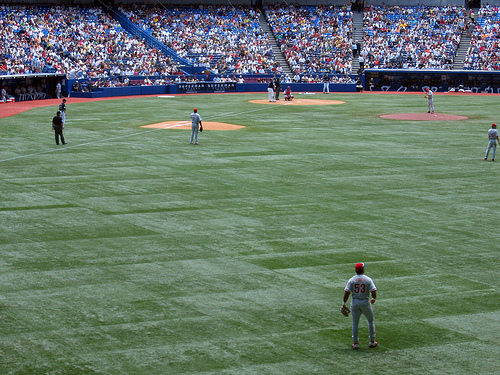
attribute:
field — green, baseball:
[99, 187, 245, 284]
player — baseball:
[319, 236, 401, 355]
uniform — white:
[331, 263, 402, 370]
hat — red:
[331, 260, 391, 290]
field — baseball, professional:
[90, 142, 255, 295]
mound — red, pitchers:
[377, 86, 471, 147]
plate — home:
[257, 86, 347, 129]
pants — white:
[382, 100, 424, 109]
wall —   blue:
[74, 100, 82, 137]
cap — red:
[328, 255, 386, 277]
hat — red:
[336, 259, 384, 274]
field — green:
[77, 130, 387, 321]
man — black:
[51, 108, 66, 147]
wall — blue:
[64, 81, 364, 96]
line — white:
[0, 100, 297, 162]